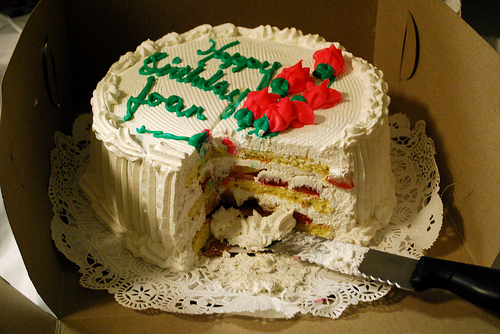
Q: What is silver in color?
A: Knife.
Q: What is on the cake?
A: Frosting.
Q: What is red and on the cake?
A: Flower frosting.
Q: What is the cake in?
A: A box.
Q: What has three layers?
A: The cake.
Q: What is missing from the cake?
A: Slice of cake.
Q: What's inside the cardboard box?
A: Cake.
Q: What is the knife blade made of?
A: Metal.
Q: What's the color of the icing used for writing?
A: Green.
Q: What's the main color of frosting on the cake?
A: White.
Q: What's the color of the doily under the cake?
A: White.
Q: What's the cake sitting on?
A: Doily.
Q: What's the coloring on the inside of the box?
A: Brown.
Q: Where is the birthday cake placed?
A: Box.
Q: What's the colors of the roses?
A: Red.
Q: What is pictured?
A: A cake.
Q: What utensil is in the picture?
A: A knife.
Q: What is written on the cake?
A: Happy Birthday Joan.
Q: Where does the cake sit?
A: Inside a box.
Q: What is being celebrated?
A: A birthday.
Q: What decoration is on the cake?
A: Red flowers.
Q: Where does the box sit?
A: On a table.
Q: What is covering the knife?
A: White frosting.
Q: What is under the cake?
A: White sheet paper.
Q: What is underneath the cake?
A: Paper.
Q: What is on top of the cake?
A: Writing.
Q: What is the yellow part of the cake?
A: Cake.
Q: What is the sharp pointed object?
A: Knife.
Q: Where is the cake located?
A: Box.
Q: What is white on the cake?
A: Frosting.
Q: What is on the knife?
A: Frosting.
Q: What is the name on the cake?
A: Joan.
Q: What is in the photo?
A: A birthday cake.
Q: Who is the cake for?
A: Joan.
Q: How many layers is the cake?
A: Three.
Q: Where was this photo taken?
A: At Joans' birthday party.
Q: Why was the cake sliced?
A: So everyone could have cake.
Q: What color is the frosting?
A: White.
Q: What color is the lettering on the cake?
A: Green.